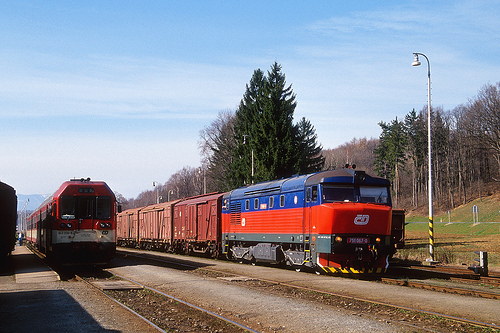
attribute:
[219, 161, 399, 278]
engine — red, blue, metal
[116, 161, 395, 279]
train — present, red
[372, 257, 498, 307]
track — silver, present, gray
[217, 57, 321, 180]
tree — green, present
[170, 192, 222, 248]
car — red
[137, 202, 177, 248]
car — red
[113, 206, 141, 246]
car — red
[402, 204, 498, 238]
grass — green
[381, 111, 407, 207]
tree — brown, present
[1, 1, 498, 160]
sky — blue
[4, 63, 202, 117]
cloud — white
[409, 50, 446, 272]
pole — tall, silver, black, yellow, light, present, curved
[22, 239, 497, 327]
track — train